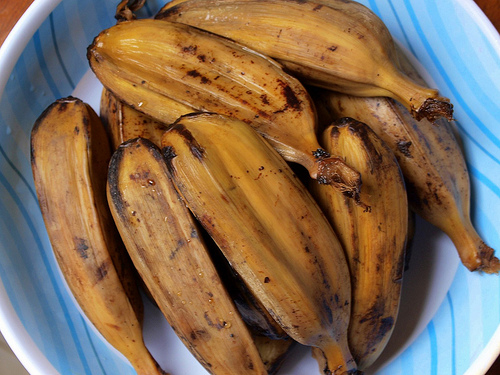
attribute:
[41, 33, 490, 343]
bananas — here, boiled, peeled, cooked, slimey, ripe, bruised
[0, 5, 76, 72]
plate — plastic, blue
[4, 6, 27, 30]
table — wooden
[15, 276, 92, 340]
bowl — blue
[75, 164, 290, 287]
plantains — corndog shaped, blacked, thick, ripe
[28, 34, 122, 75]
paint — blue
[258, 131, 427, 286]
fruit — ripe, tropical, focused, brown